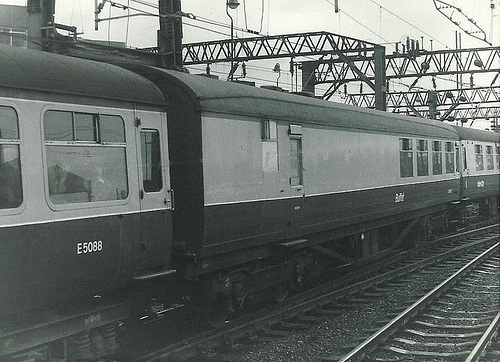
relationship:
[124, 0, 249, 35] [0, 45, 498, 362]
wire behind train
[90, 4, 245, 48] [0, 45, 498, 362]
wire behind train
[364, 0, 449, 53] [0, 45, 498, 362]
wire behind train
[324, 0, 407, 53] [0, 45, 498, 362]
wire behind train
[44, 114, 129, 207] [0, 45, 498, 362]
window on side of train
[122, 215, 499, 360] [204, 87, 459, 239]
railway tracks on side of train car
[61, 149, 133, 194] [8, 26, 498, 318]
people are inside train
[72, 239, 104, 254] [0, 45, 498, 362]
number on side of train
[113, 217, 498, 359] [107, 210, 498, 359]
gravel between tracks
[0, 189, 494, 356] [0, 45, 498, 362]
wheels under train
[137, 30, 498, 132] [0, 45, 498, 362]
scaffolding above train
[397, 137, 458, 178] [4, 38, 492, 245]
windows on side of train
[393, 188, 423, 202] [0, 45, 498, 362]
number on side of train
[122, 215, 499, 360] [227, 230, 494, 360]
railway tracks on side of gravel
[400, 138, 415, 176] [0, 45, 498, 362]
window on train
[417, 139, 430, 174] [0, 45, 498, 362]
window on train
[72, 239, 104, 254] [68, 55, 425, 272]
number on train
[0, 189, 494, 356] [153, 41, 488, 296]
wheels on train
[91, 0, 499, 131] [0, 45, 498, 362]
power lines on train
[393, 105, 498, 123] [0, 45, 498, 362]
metal beam over train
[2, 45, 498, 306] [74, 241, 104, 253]
train with white number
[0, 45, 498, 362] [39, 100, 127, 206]
train with window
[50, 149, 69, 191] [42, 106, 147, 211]
girl in window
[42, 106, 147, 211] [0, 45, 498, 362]
window of train